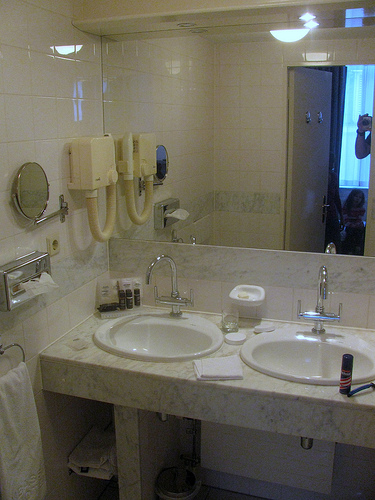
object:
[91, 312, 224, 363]
sink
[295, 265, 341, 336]
faucet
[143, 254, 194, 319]
faucet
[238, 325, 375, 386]
sink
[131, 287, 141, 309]
toiletries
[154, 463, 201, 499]
plastic bag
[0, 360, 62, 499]
towel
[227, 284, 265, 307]
dish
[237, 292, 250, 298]
soap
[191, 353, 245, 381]
cloth rag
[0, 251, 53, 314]
holder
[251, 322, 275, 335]
soap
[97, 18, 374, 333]
wall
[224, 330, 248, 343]
container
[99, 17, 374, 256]
mirror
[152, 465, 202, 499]
can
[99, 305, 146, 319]
tray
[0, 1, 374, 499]
bathroom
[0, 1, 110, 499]
wall